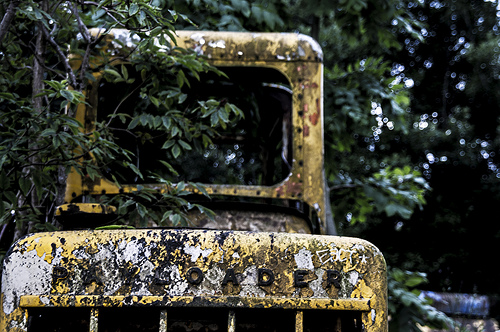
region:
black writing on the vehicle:
[48, 260, 349, 292]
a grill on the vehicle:
[24, 297, 368, 329]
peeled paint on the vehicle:
[0, 238, 60, 312]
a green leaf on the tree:
[168, 142, 183, 160]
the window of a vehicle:
[80, 55, 297, 190]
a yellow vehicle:
[1, 20, 393, 330]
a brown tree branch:
[21, 28, 59, 173]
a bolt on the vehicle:
[293, 122, 305, 137]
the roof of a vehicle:
[76, 25, 326, 75]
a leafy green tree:
[1, 0, 498, 330]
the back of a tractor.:
[2, 226, 421, 329]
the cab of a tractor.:
[50, 16, 329, 228]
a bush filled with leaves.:
[348, 148, 453, 240]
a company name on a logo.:
[43, 261, 363, 303]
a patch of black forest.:
[450, 193, 495, 249]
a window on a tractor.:
[78, 63, 295, 196]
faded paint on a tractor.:
[7, 244, 399, 303]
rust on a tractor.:
[247, 174, 319, 214]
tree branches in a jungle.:
[20, 1, 75, 149]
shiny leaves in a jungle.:
[369, 49, 405, 157]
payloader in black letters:
[45, 262, 345, 288]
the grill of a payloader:
[12, 286, 377, 326]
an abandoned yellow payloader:
[2, 26, 387, 326]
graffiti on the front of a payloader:
[311, 236, 376, 266]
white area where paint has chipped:
[2, 240, 57, 302]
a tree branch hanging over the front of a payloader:
[27, 31, 79, 116]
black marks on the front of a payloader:
[151, 225, 186, 252]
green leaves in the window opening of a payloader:
[136, 40, 233, 150]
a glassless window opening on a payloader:
[65, 50, 315, 195]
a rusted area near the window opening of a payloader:
[274, 166, 305, 197]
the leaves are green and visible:
[78, 20, 272, 291]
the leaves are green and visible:
[71, 61, 178, 229]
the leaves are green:
[73, 73, 203, 183]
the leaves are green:
[99, 63, 236, 251]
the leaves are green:
[46, 40, 268, 328]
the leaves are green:
[95, 104, 178, 211]